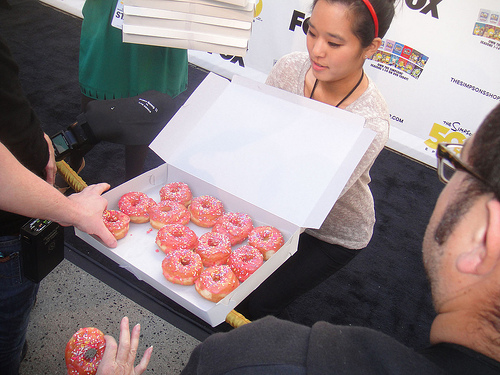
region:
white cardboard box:
[171, 109, 317, 305]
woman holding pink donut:
[67, 327, 124, 371]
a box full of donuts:
[142, 207, 280, 280]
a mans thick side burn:
[418, 189, 486, 268]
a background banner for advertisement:
[444, 39, 480, 128]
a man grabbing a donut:
[64, 162, 108, 254]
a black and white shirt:
[97, 68, 163, 130]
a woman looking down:
[284, 0, 397, 97]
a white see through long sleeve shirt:
[351, 175, 382, 249]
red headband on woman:
[343, 0, 384, 52]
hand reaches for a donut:
[39, 17, 359, 353]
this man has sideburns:
[394, 88, 495, 274]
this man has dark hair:
[411, 83, 493, 231]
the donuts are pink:
[173, 179, 302, 342]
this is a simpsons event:
[419, 85, 479, 193]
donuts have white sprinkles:
[159, 199, 365, 354]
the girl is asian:
[288, 11, 331, 85]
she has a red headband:
[291, 8, 436, 138]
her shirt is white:
[280, 11, 405, 176]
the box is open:
[100, 18, 350, 320]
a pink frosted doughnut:
[65, 325, 102, 370]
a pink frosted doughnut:
[160, 245, 200, 280]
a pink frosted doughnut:
[195, 260, 235, 300]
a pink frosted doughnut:
[227, 245, 258, 281]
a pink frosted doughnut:
[196, 227, 227, 263]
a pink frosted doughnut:
[156, 224, 194, 251]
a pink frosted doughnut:
[104, 207, 129, 241]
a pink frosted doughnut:
[119, 190, 156, 223]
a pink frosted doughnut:
[152, 200, 188, 229]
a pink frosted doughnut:
[156, 181, 191, 205]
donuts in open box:
[77, 69, 368, 322]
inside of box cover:
[163, 71, 368, 228]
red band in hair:
[358, 0, 385, 41]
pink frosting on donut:
[159, 224, 194, 249]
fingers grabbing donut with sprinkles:
[68, 181, 120, 250]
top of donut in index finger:
[72, 327, 114, 373]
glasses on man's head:
[435, 142, 499, 194]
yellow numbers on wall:
[423, 124, 466, 158]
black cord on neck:
[303, 68, 366, 111]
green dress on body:
[73, 8, 185, 110]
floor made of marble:
[62, 320, 74, 333]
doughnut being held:
[69, 326, 110, 363]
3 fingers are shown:
[114, 307, 171, 373]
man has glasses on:
[428, 118, 491, 208]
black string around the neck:
[297, 58, 383, 128]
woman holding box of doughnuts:
[234, 45, 372, 260]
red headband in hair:
[324, 0, 410, 55]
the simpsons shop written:
[443, 63, 499, 103]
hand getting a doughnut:
[35, 173, 139, 273]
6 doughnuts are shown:
[198, 190, 299, 327]